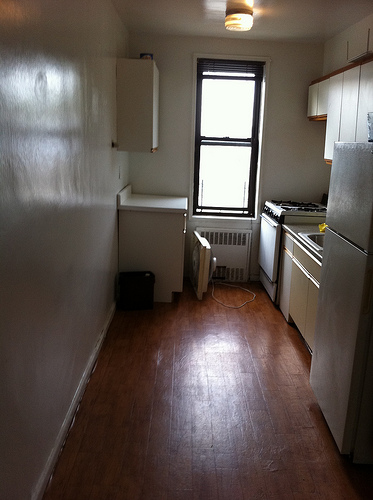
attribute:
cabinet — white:
[112, 55, 178, 159]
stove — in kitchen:
[257, 187, 325, 302]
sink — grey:
[296, 229, 324, 252]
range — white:
[255, 197, 326, 304]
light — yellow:
[224, 12, 253, 31]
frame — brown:
[191, 55, 260, 216]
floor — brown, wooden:
[175, 311, 271, 435]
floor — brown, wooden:
[106, 316, 313, 479]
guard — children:
[200, 180, 251, 213]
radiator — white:
[185, 221, 254, 282]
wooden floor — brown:
[51, 279, 371, 499]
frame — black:
[193, 56, 266, 217]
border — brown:
[305, 57, 358, 120]